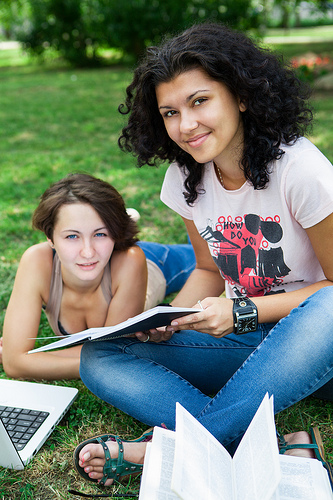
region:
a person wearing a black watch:
[232, 293, 253, 336]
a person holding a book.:
[29, 304, 226, 353]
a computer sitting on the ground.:
[0, 372, 70, 466]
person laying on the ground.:
[23, 187, 181, 305]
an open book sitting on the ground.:
[147, 423, 309, 497]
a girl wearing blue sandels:
[81, 425, 161, 475]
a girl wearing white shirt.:
[163, 173, 331, 277]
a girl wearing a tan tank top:
[28, 263, 144, 306]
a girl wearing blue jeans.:
[75, 357, 331, 417]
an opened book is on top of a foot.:
[145, 429, 331, 480]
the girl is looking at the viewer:
[35, 174, 125, 283]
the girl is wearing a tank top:
[27, 175, 144, 346]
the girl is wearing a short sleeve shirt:
[161, 137, 330, 314]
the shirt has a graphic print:
[197, 211, 290, 301]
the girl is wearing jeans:
[83, 292, 331, 460]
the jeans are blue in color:
[85, 286, 327, 459]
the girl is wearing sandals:
[71, 423, 175, 485]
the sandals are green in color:
[78, 428, 168, 488]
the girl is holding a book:
[22, 306, 195, 354]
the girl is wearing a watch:
[228, 292, 257, 330]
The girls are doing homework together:
[4, 18, 330, 492]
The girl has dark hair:
[79, 11, 313, 206]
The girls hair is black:
[115, 18, 314, 186]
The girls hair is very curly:
[111, 22, 316, 205]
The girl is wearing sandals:
[66, 421, 157, 486]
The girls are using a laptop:
[0, 357, 72, 481]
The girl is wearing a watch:
[217, 284, 274, 336]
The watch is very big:
[227, 287, 265, 341]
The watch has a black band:
[230, 287, 266, 343]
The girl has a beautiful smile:
[146, 72, 237, 167]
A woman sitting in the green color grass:
[136, 59, 313, 484]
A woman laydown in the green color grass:
[25, 171, 147, 295]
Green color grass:
[24, 83, 73, 128]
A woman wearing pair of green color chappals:
[80, 439, 304, 461]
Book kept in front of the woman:
[171, 430, 307, 486]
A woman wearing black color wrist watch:
[233, 293, 258, 339]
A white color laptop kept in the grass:
[4, 377, 64, 445]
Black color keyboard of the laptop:
[7, 410, 29, 426]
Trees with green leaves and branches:
[24, 1, 130, 37]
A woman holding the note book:
[86, 300, 205, 340]